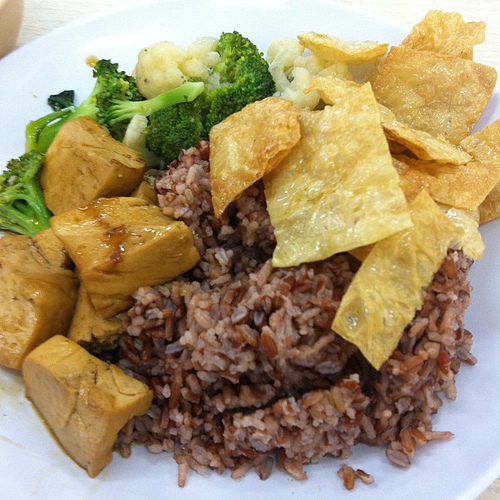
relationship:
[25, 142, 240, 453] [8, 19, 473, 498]
meat on plate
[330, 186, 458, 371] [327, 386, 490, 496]
chip on plate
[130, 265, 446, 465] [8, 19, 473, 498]
rice on plate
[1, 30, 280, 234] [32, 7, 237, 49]
broccoli on plate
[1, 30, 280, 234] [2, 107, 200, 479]
broccoli near chicken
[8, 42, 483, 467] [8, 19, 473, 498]
food on plate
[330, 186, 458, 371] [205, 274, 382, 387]
chip on rice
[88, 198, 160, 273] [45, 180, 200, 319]
sauce on chicken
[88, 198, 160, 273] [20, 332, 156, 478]
sauce on chicken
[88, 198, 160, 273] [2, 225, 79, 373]
sauce on chicken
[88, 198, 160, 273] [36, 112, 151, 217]
sauce on chicken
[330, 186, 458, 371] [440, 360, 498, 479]
chip on plate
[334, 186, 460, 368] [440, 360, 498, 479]
chip on plate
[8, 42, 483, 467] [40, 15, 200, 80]
food on white plate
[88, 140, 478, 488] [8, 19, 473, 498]
rice on plate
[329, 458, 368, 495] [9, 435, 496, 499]
pieces on plate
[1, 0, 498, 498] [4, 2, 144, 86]
plate on table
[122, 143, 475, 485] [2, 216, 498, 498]
pile on white plate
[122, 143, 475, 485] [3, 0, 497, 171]
pile on white plate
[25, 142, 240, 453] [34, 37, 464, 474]
meat on plate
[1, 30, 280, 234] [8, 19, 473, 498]
broccoli on lunch plate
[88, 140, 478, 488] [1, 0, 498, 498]
rice on plate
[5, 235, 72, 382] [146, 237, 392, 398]
chunk over rice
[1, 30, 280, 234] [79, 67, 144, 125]
broccoli and broccoli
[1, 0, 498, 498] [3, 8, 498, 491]
plate with food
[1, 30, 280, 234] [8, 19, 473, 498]
broccoli on plate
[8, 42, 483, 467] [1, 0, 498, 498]
food on plate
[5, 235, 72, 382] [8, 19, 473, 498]
chunk of meat on plate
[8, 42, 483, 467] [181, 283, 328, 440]
food on top of rice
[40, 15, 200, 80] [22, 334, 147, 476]
white plate with food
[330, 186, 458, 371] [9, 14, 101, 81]
chip on dish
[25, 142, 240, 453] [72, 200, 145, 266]
meat has sauce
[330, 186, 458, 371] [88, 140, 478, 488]
chip are over rice